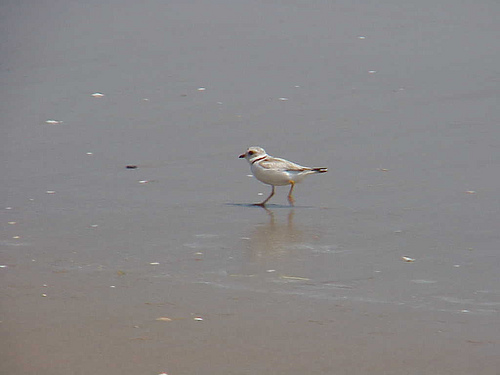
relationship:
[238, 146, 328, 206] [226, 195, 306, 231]
bird walking in dirt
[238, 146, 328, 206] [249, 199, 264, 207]
bird has foot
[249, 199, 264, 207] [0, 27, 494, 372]
foot in sand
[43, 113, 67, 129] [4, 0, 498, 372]
seashells are on beach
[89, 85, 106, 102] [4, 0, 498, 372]
seashells are on beach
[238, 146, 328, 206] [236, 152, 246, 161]
bird has beak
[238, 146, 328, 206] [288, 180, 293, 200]
bird has leg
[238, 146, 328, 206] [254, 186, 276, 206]
bird has leg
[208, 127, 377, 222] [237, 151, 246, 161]
bird with beak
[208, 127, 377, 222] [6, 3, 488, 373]
bird walking in dirt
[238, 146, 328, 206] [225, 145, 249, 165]
bird with beak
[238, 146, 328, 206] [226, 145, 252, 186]
bird with beak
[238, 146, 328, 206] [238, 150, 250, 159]
bird with beak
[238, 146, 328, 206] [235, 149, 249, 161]
bird in beak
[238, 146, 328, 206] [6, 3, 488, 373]
bird in dirt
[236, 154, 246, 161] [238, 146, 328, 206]
beak on bird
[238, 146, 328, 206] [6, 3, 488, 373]
bird walking on dirt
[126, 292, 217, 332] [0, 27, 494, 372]
seashells in sand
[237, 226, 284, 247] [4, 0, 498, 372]
sand on beach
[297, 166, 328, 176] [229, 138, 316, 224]
feathers on bird